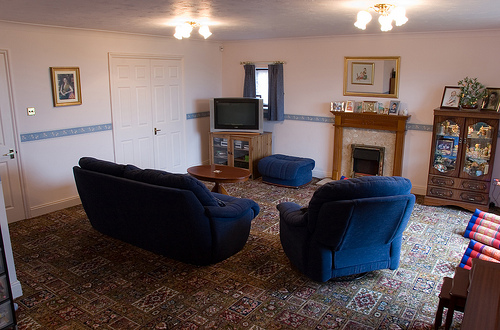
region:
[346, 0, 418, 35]
the lights are turned on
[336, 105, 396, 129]
the mantel is brown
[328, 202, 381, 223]
the chair is blue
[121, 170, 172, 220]
the couch is blue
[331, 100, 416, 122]
the pictures are on the mantel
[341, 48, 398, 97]
the picture is reflecting in the mirror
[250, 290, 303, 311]
the carpet is multi color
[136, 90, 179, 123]
the doors are white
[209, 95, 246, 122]
the tv is silver and black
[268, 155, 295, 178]
the ottoman is blue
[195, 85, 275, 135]
Television in corner of room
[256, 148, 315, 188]
Blue upholstered foot stool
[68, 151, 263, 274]
Blue upholstered love seat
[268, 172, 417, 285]
Blue upholstered reclining rocking chair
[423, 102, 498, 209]
Glass door display cabinet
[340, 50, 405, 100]
Wood framed mirror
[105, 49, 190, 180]
Double six panel doors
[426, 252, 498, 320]
Wood nesting side tables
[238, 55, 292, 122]
Blue window curtains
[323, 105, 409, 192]
Fire place with wood mantel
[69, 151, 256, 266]
a dark blue couch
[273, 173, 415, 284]
a dark blue rocking chair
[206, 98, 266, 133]
a silver television set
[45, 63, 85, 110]
framed picture on wall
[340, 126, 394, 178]
a white stone fire place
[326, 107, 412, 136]
a brown wooden mantle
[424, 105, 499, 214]
a brown wood curio cabinet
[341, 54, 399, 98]
a gold framed mirror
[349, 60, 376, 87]
reflection of a framed print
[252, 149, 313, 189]
a dark blue ottoman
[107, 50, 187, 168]
white double-doors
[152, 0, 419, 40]
two light fixtures with three lamps each on ceiling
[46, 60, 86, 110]
framed photograph of a woman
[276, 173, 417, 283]
a dark blue recliner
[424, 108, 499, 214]
items inside a wooden curio cabinet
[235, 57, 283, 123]
dark blue curtains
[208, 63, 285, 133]
flat screen television in front of window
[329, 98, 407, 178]
framed items on wooden mantlepiece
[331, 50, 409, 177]
mirror above mantlepiece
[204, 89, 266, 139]
A FLAT SCREEN TV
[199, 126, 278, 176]
A WOODEN TV CABINET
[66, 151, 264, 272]
A BLUE LIVING ROOM SOFA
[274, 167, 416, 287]
A BLUE LIVING ROOM CHAIR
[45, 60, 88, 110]
A PICTURE ON A WALL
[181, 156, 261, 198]
A BROWN WOODEN COFFEE TABLE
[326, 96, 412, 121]
PICTURES ON THE MANTEL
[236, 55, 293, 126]
A PAIR OF CURTAINS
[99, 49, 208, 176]
TWO WHITE DOORS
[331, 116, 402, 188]
A FIRE PLACE